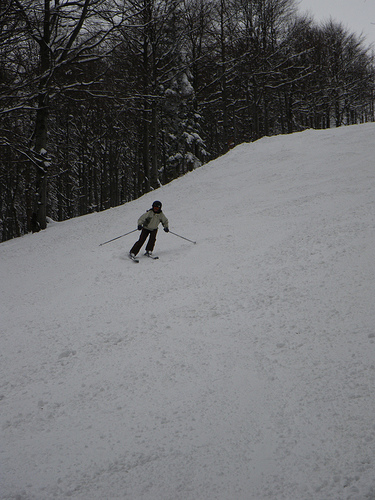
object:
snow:
[2, 119, 374, 500]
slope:
[2, 118, 374, 499]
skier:
[126, 200, 170, 264]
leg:
[129, 231, 148, 258]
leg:
[145, 229, 157, 256]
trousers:
[130, 228, 157, 253]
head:
[149, 199, 165, 215]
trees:
[316, 2, 368, 123]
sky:
[3, 0, 375, 55]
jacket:
[138, 212, 170, 232]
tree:
[151, 6, 209, 177]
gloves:
[164, 224, 171, 234]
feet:
[148, 251, 158, 259]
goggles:
[157, 206, 161, 208]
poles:
[99, 229, 137, 248]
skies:
[147, 251, 161, 264]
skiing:
[100, 201, 202, 272]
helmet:
[153, 199, 162, 202]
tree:
[1, 1, 119, 237]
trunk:
[33, 101, 48, 233]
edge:
[128, 252, 137, 262]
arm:
[160, 212, 171, 231]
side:
[139, 210, 151, 228]